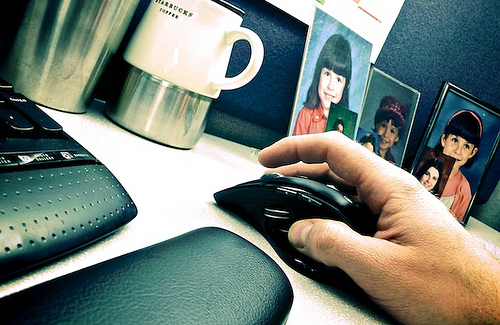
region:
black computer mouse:
[214, 167, 388, 293]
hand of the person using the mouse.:
[248, 130, 463, 323]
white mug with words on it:
[110, 0, 267, 102]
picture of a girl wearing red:
[287, 0, 372, 189]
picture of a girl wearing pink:
[426, 83, 498, 240]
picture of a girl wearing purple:
[354, 62, 420, 179]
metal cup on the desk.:
[9, 0, 148, 115]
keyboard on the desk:
[0, 76, 141, 286]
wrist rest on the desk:
[1, 228, 294, 323]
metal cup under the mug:
[104, 58, 218, 153]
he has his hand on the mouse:
[310, 146, 372, 263]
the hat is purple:
[391, 102, 405, 115]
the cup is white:
[178, 65, 205, 83]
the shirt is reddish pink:
[303, 115, 319, 130]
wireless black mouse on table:
[214, 139, 393, 254]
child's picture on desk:
[280, 7, 382, 158]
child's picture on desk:
[424, 80, 486, 237]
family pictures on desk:
[266, 21, 498, 228]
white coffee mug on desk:
[139, 0, 266, 122]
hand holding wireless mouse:
[211, 121, 422, 321]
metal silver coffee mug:
[8, 0, 134, 121]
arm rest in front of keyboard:
[20, 228, 299, 323]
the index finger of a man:
[246, 120, 364, 178]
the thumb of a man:
[271, 200, 412, 302]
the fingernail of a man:
[283, 214, 335, 241]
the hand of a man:
[226, 140, 478, 301]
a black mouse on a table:
[226, 118, 432, 273]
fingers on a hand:
[247, 73, 422, 195]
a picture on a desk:
[270, 0, 375, 152]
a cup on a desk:
[113, 0, 274, 185]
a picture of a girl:
[286, 0, 442, 141]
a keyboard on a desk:
[16, 2, 287, 273]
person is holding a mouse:
[225, 96, 464, 311]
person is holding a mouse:
[247, 140, 416, 285]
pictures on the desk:
[292, 22, 494, 236]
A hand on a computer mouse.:
[209, 122, 454, 321]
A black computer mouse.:
[219, 167, 396, 299]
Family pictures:
[278, 0, 498, 231]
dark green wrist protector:
[0, 224, 295, 321]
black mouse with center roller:
[213, 168, 378, 292]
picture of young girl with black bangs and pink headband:
[410, 80, 498, 231]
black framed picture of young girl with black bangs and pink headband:
[408, 79, 498, 228]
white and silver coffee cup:
[105, 0, 265, 150]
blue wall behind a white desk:
[201, 0, 498, 230]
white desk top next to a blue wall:
[5, 87, 498, 324]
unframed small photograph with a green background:
[323, 100, 360, 142]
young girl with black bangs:
[289, 32, 351, 142]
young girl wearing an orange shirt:
[290, 29, 352, 146]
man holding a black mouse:
[213, 153, 388, 281]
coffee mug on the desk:
[135, 0, 265, 152]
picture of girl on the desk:
[290, 1, 356, 172]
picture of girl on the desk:
[352, 58, 421, 198]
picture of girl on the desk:
[410, 72, 495, 243]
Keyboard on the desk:
[0, 65, 143, 269]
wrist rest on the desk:
[16, 215, 297, 323]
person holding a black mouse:
[211, 165, 360, 262]